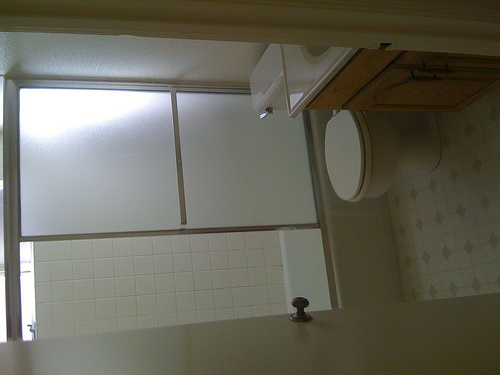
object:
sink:
[283, 42, 365, 120]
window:
[7, 59, 453, 296]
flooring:
[459, 93, 499, 141]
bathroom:
[1, 27, 499, 338]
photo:
[0, 0, 499, 372]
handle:
[289, 297, 314, 323]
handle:
[257, 105, 277, 120]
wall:
[156, 201, 318, 313]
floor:
[462, 263, 498, 302]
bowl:
[310, 110, 395, 203]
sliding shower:
[6, 28, 374, 373]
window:
[20, 46, 235, 153]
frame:
[3, 76, 322, 239]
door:
[4, 294, 497, 367]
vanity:
[277, 43, 356, 118]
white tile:
[115, 233, 151, 254]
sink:
[239, 37, 277, 106]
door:
[16, 83, 325, 243]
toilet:
[323, 106, 443, 201]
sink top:
[269, 22, 364, 98]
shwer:
[18, 89, 313, 337]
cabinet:
[302, 48, 499, 118]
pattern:
[358, 254, 422, 304]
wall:
[78, 241, 185, 339]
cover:
[325, 110, 368, 203]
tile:
[30, 294, 80, 338]